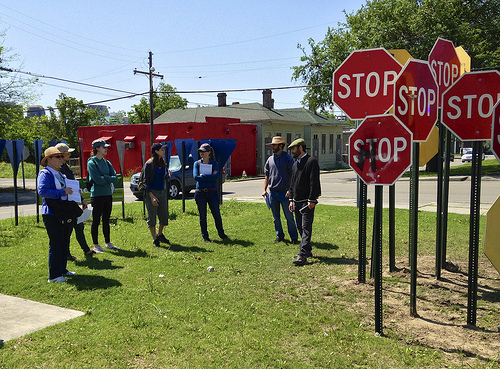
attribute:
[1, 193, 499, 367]
grass — green, grassy,  grass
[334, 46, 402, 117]
sign — red, close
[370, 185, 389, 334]
post — green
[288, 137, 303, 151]
hat — green, on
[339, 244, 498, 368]
dirt — brown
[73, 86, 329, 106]
line — electrical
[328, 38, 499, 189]
signs — multiple, many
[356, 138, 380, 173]
graffiti — black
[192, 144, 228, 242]
woman — standing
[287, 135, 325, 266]
man — standing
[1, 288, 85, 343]
block — gray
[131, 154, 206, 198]
truck — dark, only one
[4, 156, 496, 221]
asphalt — black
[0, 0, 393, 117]
sky — blue, the sky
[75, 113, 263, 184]
building — red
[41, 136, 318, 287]
people — standing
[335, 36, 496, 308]
these — signposts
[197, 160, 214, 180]
paper — white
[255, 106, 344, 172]
house — yellow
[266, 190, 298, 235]
jean — blue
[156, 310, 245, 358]
area —  gras